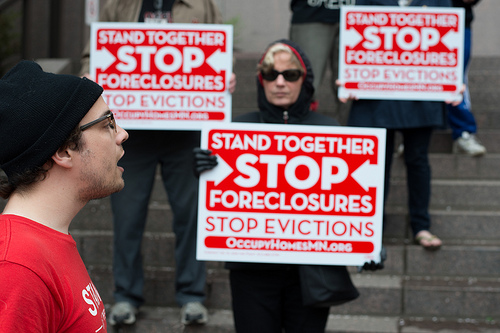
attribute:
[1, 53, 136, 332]
man — standing, speaking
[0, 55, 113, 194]
cap — black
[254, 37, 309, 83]
hair — blonde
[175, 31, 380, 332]
woman — standing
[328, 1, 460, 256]
woman — standing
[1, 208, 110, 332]
shirt — red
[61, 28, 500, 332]
stairs — occupied, gray, concrete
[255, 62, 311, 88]
sunglasses — dark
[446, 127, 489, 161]
shoe — white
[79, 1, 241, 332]
man — standing, protesting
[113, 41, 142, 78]
letter — white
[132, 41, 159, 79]
letter — white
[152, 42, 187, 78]
letter — white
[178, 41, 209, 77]
letter — white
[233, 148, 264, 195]
letter — white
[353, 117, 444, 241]
pants — dark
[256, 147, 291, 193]
letter — white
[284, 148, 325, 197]
letter — white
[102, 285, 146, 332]
shoe — gray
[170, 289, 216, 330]
shoe — gray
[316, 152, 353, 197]
letter — white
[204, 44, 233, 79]
arrow — white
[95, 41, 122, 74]
arrow — white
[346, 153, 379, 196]
arrow — white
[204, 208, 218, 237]
letter — red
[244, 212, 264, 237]
letter — red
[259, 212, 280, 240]
letter — red